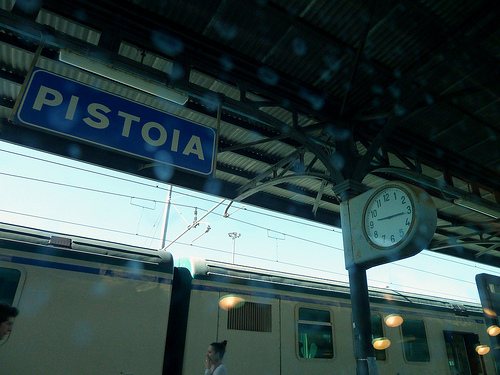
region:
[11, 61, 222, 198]
Blue and white sign that says pistoia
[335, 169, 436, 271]
round clock with numbers on steel beam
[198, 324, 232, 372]
lady walking near train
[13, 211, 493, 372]
white train with blue stripe on top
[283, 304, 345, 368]
window on train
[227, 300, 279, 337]
vent on train car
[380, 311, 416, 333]
reflection of round light on train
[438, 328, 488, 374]
open doors on train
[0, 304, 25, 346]
man walking in front of train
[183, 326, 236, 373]
woman with hand over her mouth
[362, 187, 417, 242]
white metal clockface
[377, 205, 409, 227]
black metal hands on clockface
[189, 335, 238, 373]
woman standing beside train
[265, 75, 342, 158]
large metal roof rafters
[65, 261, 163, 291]
blue stripe on side of train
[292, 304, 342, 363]
window on side of train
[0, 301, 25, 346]
man with dark short hair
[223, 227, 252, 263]
silver metal street light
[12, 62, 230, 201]
blue metal sign hanging above train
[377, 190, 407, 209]
black numbers on clock face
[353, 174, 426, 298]
A large clock on a pole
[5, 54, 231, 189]
A large blue and white sign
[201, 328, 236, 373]
A dark haired woman with her hair in a bun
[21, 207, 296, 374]
A white train with blue stripes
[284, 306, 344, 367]
A window on a train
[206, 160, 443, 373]
A clock at a train station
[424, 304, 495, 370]
Door on a train car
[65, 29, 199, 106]
A fluorescent light fixture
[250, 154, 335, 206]
Metal support for an awning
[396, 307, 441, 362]
A window on the train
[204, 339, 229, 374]
Woman with her hands on her face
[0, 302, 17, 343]
Mans face faced towards a woman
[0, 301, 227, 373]
Woman excited to see the man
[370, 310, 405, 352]
Reflection of subway lighting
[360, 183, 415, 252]
White analog clock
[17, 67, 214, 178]
Blue metal hanging sign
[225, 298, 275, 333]
Outer vent on a subway train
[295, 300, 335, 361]
Window on a subway train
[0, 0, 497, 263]
Large metal overpass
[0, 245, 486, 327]
Blue strip on the length of the tram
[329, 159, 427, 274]
A clock mounted to a pole.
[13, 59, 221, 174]
A sign in a foreign language.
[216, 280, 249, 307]
a light near a wall.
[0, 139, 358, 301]
a large window.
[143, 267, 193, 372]
a line painted on a wall.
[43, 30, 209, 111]
a light mounted to a ceiling.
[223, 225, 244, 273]
a tall parking lot light.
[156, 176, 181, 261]
a very tall power pole.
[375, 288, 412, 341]
a light near a wall.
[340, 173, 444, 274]
A wall mounted clock.